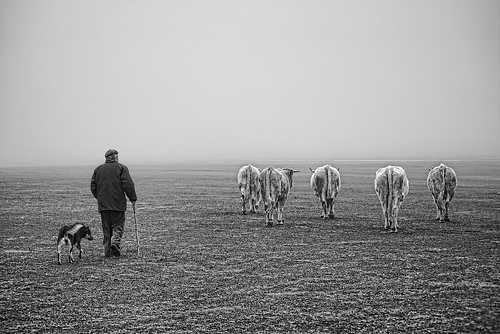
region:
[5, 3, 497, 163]
cloud cover in sky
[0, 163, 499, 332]
field with short grass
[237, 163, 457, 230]
back of walking cows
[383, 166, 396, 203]
tail on back of cow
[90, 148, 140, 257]
man walking with stick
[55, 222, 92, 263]
dog walking on grass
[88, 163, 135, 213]
waist length coat on man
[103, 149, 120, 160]
hat on man's head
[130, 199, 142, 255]
stick in man's hand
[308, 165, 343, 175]
tips of cow horns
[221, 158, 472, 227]
Cows are walking in ground.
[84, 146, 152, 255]
Man is walking in ground.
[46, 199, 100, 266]
Dog is walking with man.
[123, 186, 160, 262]
Man is holding walking stick.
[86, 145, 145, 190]
Man is wearing cap.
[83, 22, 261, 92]
Sky is grey color.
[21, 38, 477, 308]
Black and white picture.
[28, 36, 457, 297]
day time picture.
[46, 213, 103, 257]
Dog is black and white color.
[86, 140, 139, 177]
the head of a man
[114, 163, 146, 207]
the arm of a man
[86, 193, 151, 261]
the legs of a man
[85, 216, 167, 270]
the feet of a man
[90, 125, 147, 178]
a man wearing a hat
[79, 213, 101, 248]
the head of a dog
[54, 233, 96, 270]
the legs of a dog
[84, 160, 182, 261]
a man with a stick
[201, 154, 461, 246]
cows in a field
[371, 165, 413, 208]
the tail of a cow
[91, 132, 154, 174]
the head of a man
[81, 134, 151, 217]
a man wearing a hat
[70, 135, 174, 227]
a man wearing a jacket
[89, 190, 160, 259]
a man wearing panrs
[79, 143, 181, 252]
a man holding a stick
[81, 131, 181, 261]
a man in a field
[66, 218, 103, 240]
the head of a dog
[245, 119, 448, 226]
cows in a field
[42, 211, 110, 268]
a dog in a field with a man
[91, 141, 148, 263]
man walking in a field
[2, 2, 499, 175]
hazy sky above a field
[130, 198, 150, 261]
cane in a man's hand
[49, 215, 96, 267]
dog walking on man's left side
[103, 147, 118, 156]
hat on man's head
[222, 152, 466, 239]
five cows walking in the field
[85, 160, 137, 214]
man's dark colored jacket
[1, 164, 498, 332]
large area of open field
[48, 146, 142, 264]
man and dog walking cattle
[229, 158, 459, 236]
light colored cattle